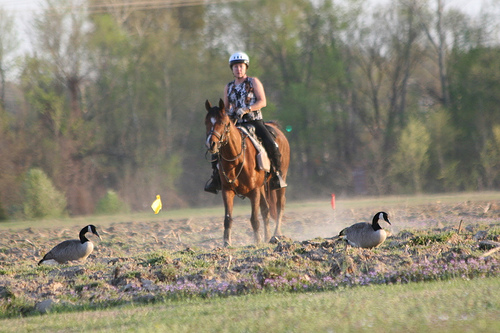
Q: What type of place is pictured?
A: It is a field.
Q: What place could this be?
A: It is a field.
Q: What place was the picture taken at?
A: It was taken at the field.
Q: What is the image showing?
A: It is showing a field.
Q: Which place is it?
A: It is a field.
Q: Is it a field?
A: Yes, it is a field.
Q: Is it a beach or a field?
A: It is a field.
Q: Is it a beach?
A: No, it is a field.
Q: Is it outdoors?
A: Yes, it is outdoors.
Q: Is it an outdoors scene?
A: Yes, it is outdoors.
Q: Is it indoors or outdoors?
A: It is outdoors.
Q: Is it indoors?
A: No, it is outdoors.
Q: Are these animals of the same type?
A: No, they are horses and birds.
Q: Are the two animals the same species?
A: No, they are horses and birds.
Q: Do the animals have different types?
A: Yes, they are horses and birds.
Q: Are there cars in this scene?
A: No, there are no cars.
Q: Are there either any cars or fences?
A: No, there are no cars or fences.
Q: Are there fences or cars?
A: No, there are no cars or fences.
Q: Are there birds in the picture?
A: Yes, there is a bird.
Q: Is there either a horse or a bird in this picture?
A: Yes, there is a bird.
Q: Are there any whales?
A: No, there are no whales.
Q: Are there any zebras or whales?
A: No, there are no whales or zebras.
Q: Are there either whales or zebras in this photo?
A: No, there are no whales or zebras.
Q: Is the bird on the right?
A: Yes, the bird is on the right of the image.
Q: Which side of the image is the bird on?
A: The bird is on the right of the image.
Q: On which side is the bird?
A: The bird is on the right of the image.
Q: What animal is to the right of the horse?
A: The animal is a bird.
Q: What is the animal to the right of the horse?
A: The animal is a bird.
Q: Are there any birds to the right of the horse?
A: Yes, there is a bird to the right of the horse.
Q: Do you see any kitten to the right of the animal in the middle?
A: No, there is a bird to the right of the horse.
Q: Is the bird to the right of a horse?
A: Yes, the bird is to the right of a horse.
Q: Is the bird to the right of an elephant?
A: No, the bird is to the right of a horse.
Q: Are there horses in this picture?
A: Yes, there is a horse.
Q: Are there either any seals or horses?
A: Yes, there is a horse.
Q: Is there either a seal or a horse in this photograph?
A: Yes, there is a horse.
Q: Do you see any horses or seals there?
A: Yes, there is a horse.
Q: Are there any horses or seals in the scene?
A: Yes, there is a horse.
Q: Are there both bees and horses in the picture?
A: No, there is a horse but no bees.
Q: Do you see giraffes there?
A: No, there are no giraffes.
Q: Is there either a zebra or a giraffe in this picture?
A: No, there are no giraffes or zebras.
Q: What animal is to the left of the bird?
A: The animal is a horse.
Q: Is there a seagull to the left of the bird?
A: No, there is a horse to the left of the bird.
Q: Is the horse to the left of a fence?
A: No, the horse is to the left of the bird.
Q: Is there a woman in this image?
A: Yes, there is a woman.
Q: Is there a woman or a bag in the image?
A: Yes, there is a woman.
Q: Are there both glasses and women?
A: No, there is a woman but no glasses.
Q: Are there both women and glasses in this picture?
A: No, there is a woman but no glasses.